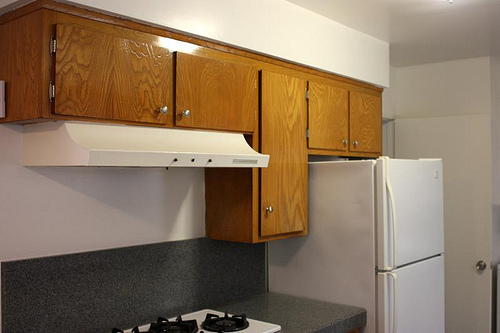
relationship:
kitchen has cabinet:
[1, 2, 499, 329] [204, 54, 311, 244]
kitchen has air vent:
[1, 2, 499, 329] [376, 115, 400, 160]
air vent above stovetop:
[19, 117, 273, 175] [98, 302, 286, 331]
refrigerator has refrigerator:
[263, 151, 448, 331] [263, 151, 448, 331]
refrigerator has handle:
[263, 151, 448, 331] [374, 149, 402, 273]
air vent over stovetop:
[376, 115, 400, 160] [98, 302, 286, 331]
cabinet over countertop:
[204, 54, 311, 244] [221, 285, 366, 329]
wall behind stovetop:
[2, 124, 210, 263] [98, 302, 286, 331]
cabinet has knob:
[204, 54, 311, 244] [263, 201, 277, 218]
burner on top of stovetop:
[198, 307, 257, 333] [98, 302, 286, 331]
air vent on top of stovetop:
[376, 115, 400, 160] [98, 302, 286, 331]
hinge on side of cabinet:
[302, 84, 311, 104] [204, 54, 311, 244]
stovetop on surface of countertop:
[98, 302, 286, 331] [221, 285, 366, 329]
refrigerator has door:
[263, 151, 448, 331] [376, 157, 447, 264]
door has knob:
[391, 108, 495, 332] [472, 255, 489, 276]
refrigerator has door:
[263, 151, 448, 331] [391, 108, 495, 332]